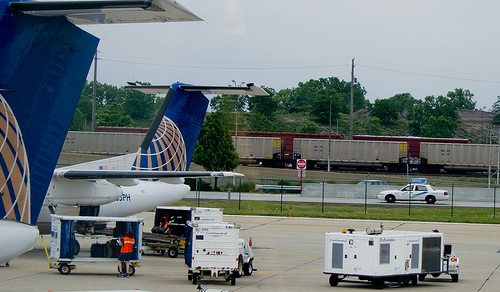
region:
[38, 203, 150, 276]
a luggage carrier trailer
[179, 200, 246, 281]
several luggage carrier trailers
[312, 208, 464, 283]
a commercial jet supply truck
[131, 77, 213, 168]
the tail-fin of a jet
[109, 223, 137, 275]
a luggage handler wearing an orange vest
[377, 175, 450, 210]
a blue and white taxi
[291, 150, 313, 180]
a Do Not Enter sign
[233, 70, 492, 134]
the foliage of several deciduous trees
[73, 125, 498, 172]
the freight cars of a freight train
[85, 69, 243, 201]
plane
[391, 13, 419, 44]
white clouds in blue sky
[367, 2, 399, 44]
white clouds in blue sky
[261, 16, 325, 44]
white clouds in blue sky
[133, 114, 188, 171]
golden globe on tail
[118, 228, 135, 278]
man wearing orange vest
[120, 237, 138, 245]
yellow stripe on vest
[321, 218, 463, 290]
the vehicle is white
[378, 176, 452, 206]
white car in background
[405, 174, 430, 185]
blue sign on car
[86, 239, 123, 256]
suitcases in the cart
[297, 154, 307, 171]
sign is red and white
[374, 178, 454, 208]
a white car on parking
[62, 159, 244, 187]
right wing of plane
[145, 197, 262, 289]
trucks on an airport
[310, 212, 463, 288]
a truck in the airport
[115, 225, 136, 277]
man wears an orange vest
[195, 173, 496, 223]
fence on green grass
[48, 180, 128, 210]
the engine under wing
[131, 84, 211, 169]
a logo on tail of plane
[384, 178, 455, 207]
Taxi near the airport runway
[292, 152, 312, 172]
do not enter sign on the pole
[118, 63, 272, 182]
Blue paint on the airplane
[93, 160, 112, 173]
american flag on a plane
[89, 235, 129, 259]
luggage in a luggage cart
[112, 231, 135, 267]
person wearing a safety vest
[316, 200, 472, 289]
work truck on the tarmac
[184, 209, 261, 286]
work truck on the tarmac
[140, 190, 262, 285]
work truck on the tarmac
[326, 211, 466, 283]
work truck on the tarmac